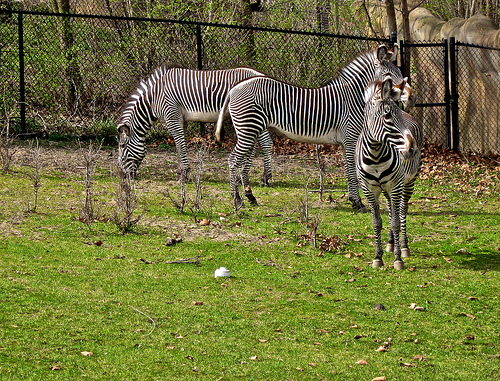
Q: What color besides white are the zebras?
A: Black.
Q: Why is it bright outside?
A: Its daytime.